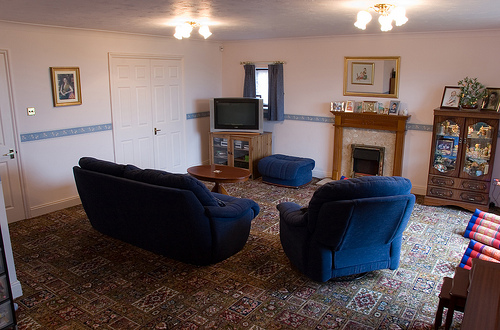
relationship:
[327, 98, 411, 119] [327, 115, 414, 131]
pictures on mantel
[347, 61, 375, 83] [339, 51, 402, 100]
picture reflecting in mirror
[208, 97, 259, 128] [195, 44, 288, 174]
television in corner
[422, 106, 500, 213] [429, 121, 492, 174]
curio cabinet has door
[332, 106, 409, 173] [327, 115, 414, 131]
fireplace with mantel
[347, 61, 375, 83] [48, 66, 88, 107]
picture on wall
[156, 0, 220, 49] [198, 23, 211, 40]
fixture with lamp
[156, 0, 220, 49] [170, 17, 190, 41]
fixture with lamp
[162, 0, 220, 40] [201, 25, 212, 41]
fixture with lamp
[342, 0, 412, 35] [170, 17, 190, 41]
fixture with lamp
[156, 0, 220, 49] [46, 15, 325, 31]
fixture on celing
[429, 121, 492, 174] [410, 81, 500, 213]
items inside curio cabinet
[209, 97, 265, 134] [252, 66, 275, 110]
television in front of window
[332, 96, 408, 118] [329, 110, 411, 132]
items on mantel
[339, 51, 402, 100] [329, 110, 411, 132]
mirror above mantel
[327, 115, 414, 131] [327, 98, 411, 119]
mantel has pictures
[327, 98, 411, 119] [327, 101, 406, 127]
pictures on mantle